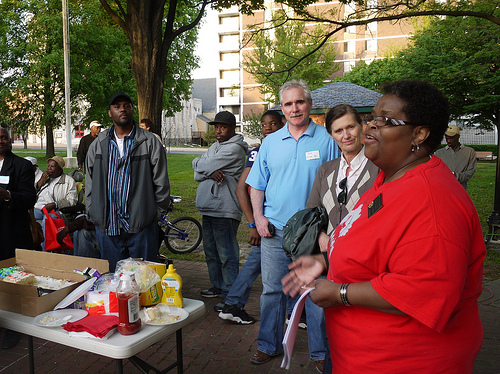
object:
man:
[83, 93, 173, 281]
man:
[187, 111, 250, 301]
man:
[244, 79, 342, 373]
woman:
[273, 79, 488, 374]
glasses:
[364, 113, 428, 129]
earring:
[411, 143, 420, 153]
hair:
[377, 74, 451, 153]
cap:
[109, 91, 134, 107]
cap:
[207, 110, 237, 128]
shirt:
[321, 156, 486, 374]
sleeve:
[367, 223, 473, 334]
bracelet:
[338, 281, 351, 308]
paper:
[277, 285, 316, 370]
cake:
[0, 260, 79, 298]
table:
[0, 254, 500, 343]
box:
[0, 248, 113, 318]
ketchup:
[116, 275, 142, 335]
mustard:
[161, 264, 186, 310]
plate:
[34, 306, 89, 327]